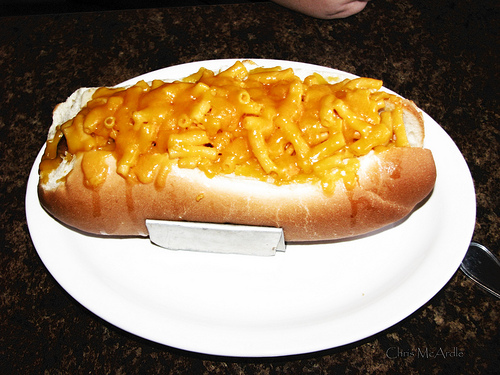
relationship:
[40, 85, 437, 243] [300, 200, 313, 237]
bun has crack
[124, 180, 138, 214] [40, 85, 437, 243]
sauce on bun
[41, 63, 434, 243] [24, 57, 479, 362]
hot dog on plate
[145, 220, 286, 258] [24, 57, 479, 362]
holder on plate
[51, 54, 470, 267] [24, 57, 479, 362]
hot dog on a plate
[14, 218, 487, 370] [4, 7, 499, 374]
plate on a table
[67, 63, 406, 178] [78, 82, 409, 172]
mac & cheese on top of hot dog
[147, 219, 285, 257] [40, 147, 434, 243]
holder propping up bun